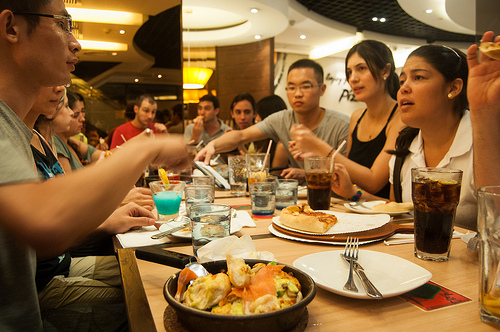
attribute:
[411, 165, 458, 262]
glass — tall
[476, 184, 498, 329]
glass — tall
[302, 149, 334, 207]
glass — tall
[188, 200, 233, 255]
glass — tall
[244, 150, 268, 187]
glass — tall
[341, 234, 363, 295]
fork — silver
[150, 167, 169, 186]
orange — sliced, perched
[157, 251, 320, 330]
bowl — black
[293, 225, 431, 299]
plate — white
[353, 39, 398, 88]
hair — dark brown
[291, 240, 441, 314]
plate — white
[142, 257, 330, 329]
bowl — black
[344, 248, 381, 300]
knife — silver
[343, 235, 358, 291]
fork — silver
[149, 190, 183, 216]
liquid — blue